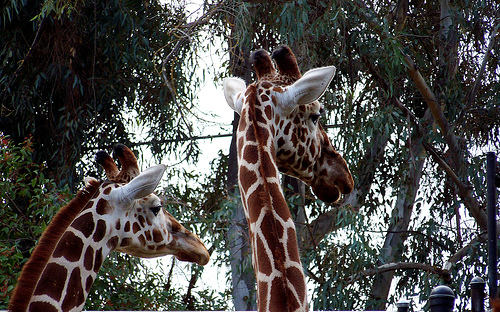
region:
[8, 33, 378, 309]
two giraffe in a zoo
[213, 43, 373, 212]
the head of a giraffe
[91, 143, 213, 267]
the head of a giraffe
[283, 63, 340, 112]
the ear of a giraffe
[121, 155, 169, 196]
the ear of a giraffe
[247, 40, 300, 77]
the horns of a giraffe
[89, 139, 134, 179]
the horns of a giraffe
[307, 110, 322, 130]
the eye of a giraffe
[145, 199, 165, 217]
the eye of a giraffe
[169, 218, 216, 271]
the nose of a giraffe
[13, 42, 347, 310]
the giraffes have long necks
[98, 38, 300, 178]
the giraffes have horns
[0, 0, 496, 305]
the giraffes are outside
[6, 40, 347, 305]
the giraffes have spots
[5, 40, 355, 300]
the giraffes are brown and white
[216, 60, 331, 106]
the giraffe has two ears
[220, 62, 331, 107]
the giraffes ears are white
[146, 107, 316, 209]
the giraffes have black eyes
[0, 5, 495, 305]
the giraffes are outdoors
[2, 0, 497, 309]
the trees have leaves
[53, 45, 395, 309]
these giraffes have white ears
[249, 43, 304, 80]
the giraffe has black tipped horns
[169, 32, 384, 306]
the giraffe appears to be about to eat leaves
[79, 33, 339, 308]
this giraffe is shorter than the other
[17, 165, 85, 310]
this giraffe has a short brown mane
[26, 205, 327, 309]
both of them have very interesting patterns on them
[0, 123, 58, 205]
these bushes have flowers on them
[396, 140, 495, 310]
a fence surrounds the area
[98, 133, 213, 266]
this giraffe looks board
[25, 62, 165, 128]
the trees are rather thick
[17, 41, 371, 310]
two necks of giraffes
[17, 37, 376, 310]
two giraffes next to each other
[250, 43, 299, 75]
brown and black horns of giraffe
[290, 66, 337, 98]
white tipped ears on giraffe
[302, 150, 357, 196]
brown and white nose of giraffe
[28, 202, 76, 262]
brown mane of giraffe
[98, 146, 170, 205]
white ear on giraffe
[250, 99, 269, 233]
long black mane of giraffe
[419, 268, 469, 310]
black metal fence post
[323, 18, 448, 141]
brown trees covered in leaves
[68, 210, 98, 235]
The spot is brown.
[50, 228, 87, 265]
The spot is brown.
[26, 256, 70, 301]
The spot is brown.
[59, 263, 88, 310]
The spot is brown.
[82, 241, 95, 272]
The spot is brown.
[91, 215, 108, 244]
The spot is brown.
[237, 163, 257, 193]
The spot is brown.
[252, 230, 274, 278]
The spot is brown.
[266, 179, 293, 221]
The spot is brown.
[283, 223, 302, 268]
The spot is brown.